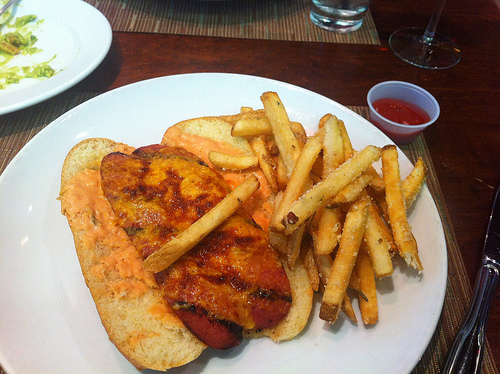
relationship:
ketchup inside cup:
[371, 94, 430, 144] [367, 77, 440, 146]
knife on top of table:
[439, 181, 497, 373] [70, 1, 498, 373]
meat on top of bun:
[97, 142, 291, 350] [59, 116, 313, 373]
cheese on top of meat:
[98, 145, 274, 330] [97, 142, 291, 350]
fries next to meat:
[144, 91, 428, 327] [97, 142, 291, 350]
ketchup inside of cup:
[371, 94, 430, 144] [367, 77, 440, 146]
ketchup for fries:
[371, 94, 430, 144] [144, 91, 428, 327]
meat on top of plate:
[97, 142, 291, 350] [1, 71, 448, 373]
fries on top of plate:
[144, 91, 428, 327] [1, 71, 448, 373]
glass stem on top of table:
[421, 1, 447, 37] [70, 1, 498, 373]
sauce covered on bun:
[62, 128, 275, 298] [59, 116, 313, 373]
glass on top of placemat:
[308, 0, 371, 34] [80, 0, 381, 47]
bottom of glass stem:
[386, 24, 463, 71] [421, 1, 447, 37]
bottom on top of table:
[386, 24, 463, 71] [70, 1, 498, 373]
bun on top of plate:
[59, 116, 313, 373] [1, 71, 448, 373]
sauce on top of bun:
[62, 128, 275, 298] [59, 116, 313, 373]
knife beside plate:
[439, 181, 497, 373] [1, 71, 448, 373]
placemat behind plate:
[80, 0, 381, 47] [1, 1, 114, 116]